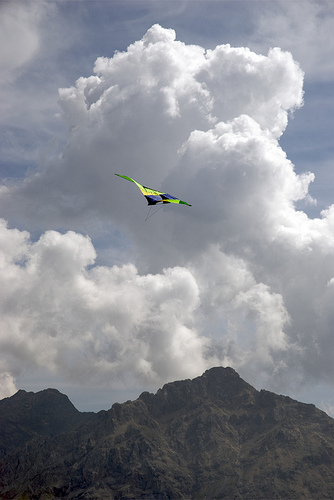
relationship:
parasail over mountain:
[124, 170, 189, 224] [22, 353, 317, 471]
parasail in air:
[115, 173, 192, 221] [67, 141, 245, 276]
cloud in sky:
[137, 50, 189, 113] [44, 74, 134, 146]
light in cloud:
[184, 49, 279, 93] [137, 50, 189, 113]